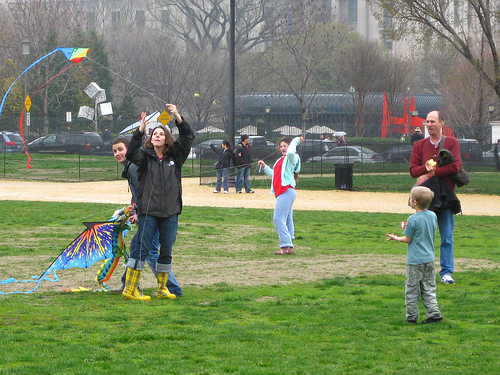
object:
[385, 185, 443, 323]
boy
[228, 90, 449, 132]
house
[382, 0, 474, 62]
branch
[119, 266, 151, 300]
boot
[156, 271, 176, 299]
boot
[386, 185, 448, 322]
child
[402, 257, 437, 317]
pants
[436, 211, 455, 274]
pants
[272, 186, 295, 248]
pants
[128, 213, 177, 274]
pants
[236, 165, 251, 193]
pants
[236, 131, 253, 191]
people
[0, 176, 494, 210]
path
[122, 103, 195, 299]
lady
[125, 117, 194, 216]
jacket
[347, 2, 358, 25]
window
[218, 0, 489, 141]
building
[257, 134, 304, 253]
woman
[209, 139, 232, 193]
woman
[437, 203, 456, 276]
jeans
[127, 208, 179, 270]
jeans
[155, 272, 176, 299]
yellow boot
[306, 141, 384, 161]
car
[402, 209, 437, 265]
shirt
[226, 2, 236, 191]
pole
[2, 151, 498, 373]
park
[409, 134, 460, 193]
shirt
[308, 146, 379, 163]
gray car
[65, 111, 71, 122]
sign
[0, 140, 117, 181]
post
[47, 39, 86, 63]
kite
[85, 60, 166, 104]
string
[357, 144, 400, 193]
fence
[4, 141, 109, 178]
fencing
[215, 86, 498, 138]
train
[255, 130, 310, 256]
girl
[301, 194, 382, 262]
ground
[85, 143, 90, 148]
tail light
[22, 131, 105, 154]
vehicle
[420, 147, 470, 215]
coat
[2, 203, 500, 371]
grass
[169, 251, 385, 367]
field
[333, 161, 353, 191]
trash bin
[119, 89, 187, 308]
woman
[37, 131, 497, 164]
road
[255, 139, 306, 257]
children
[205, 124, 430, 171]
parking lot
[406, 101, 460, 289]
man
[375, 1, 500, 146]
tree